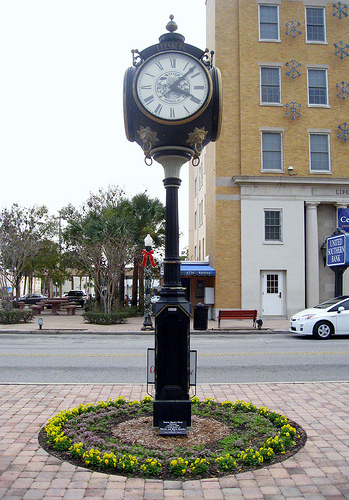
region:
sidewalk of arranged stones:
[0, 461, 64, 496]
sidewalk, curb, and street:
[0, 368, 86, 391]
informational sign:
[145, 400, 199, 438]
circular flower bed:
[34, 390, 308, 479]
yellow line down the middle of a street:
[9, 336, 123, 362]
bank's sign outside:
[313, 214, 343, 292]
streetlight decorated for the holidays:
[134, 230, 154, 326]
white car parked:
[288, 283, 340, 337]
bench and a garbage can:
[190, 285, 258, 330]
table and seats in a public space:
[15, 268, 102, 321]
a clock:
[92, 50, 270, 145]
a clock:
[33, 16, 260, 191]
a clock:
[119, 6, 217, 134]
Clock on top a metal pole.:
[120, 7, 227, 436]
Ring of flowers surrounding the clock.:
[36, 389, 309, 483]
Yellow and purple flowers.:
[36, 397, 303, 482]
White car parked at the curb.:
[289, 294, 347, 341]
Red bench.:
[217, 306, 258, 330]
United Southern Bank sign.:
[322, 233, 347, 298]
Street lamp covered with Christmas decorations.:
[138, 232, 157, 330]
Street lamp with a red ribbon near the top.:
[138, 232, 155, 328]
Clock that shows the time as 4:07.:
[121, 11, 223, 160]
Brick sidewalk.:
[0, 377, 348, 498]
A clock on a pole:
[130, 37, 225, 145]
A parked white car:
[286, 289, 348, 330]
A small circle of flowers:
[43, 391, 292, 471]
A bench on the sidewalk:
[216, 304, 260, 328]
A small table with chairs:
[31, 295, 80, 313]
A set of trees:
[87, 190, 147, 320]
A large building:
[188, 1, 345, 319]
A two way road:
[1, 334, 324, 374]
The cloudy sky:
[0, 3, 171, 200]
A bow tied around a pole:
[140, 246, 155, 265]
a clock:
[112, 30, 236, 190]